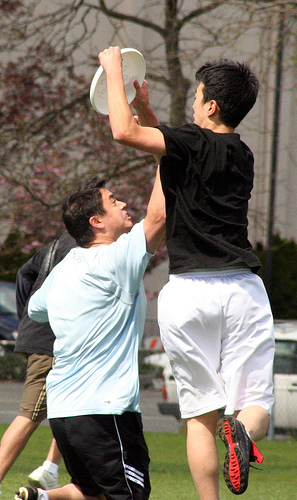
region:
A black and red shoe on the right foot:
[220, 417, 250, 493]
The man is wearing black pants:
[49, 413, 149, 499]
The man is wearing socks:
[43, 460, 57, 471]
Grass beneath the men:
[1, 423, 295, 499]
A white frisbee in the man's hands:
[90, 48, 146, 116]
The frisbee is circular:
[90, 49, 146, 116]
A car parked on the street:
[160, 320, 295, 432]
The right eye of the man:
[109, 196, 115, 203]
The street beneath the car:
[1, 380, 295, 438]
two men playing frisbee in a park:
[26, 45, 274, 497]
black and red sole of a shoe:
[216, 415, 248, 494]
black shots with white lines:
[48, 414, 152, 498]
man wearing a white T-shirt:
[27, 218, 158, 418]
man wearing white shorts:
[157, 269, 273, 420]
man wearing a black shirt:
[155, 119, 259, 273]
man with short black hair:
[192, 58, 258, 130]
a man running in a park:
[0, 178, 104, 497]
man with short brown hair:
[62, 175, 129, 239]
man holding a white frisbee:
[89, 45, 275, 496]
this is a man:
[36, 172, 131, 484]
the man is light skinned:
[109, 208, 124, 222]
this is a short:
[170, 308, 257, 380]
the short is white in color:
[198, 313, 217, 355]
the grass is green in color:
[157, 438, 185, 471]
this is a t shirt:
[166, 141, 247, 253]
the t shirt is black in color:
[191, 191, 230, 245]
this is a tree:
[17, 28, 67, 160]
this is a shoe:
[221, 417, 248, 485]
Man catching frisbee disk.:
[78, 30, 282, 498]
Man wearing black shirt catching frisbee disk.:
[77, 31, 283, 498]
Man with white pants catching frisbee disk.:
[74, 33, 278, 498]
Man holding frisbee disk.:
[76, 31, 278, 496]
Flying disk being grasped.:
[73, 31, 279, 498]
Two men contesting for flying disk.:
[3, 39, 279, 497]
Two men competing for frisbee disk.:
[4, 32, 277, 498]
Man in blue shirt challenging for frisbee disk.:
[6, 31, 279, 498]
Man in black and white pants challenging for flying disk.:
[6, 35, 285, 498]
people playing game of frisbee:
[23, 29, 258, 494]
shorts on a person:
[40, 410, 160, 496]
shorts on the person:
[150, 264, 280, 415]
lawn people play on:
[6, 424, 296, 494]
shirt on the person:
[162, 129, 252, 266]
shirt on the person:
[21, 234, 155, 416]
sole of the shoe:
[219, 421, 246, 484]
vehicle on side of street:
[149, 320, 292, 436]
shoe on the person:
[28, 463, 62, 488]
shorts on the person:
[10, 352, 60, 423]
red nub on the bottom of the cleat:
[220, 422, 225, 425]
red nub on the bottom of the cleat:
[222, 426, 230, 434]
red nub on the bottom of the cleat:
[227, 451, 232, 452]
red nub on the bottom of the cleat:
[228, 453, 233, 456]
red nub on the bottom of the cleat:
[228, 459, 234, 463]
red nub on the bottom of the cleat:
[227, 464, 232, 470]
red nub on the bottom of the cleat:
[232, 468, 236, 471]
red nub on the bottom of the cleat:
[228, 471, 232, 473]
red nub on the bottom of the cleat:
[229, 470, 240, 477]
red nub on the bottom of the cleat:
[232, 478, 236, 482]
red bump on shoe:
[224, 421, 229, 426]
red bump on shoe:
[224, 424, 229, 430]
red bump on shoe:
[224, 430, 229, 435]